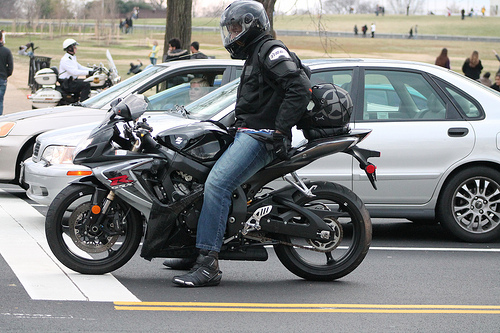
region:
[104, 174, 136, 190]
red R on the side of the motor bike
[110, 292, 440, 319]
double yellow line on the street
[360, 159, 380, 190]
red light on the back of bike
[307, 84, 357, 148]
extra helmet tied to the back of motorcycle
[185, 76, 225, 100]
woman with blonde hair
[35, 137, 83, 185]
front headlights are on in the front of car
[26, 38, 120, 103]
policeman riding on a motorcycle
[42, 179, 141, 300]
front black wheel on the white line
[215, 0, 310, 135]
rider is wearing a black jacket and helmet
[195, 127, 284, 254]
rider on motor bike is wearing blue jeans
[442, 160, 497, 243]
rear left tire on car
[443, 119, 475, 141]
black handle on door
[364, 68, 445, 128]
back window on car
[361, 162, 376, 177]
red light on back of motorcycle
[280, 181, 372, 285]
back tire on bike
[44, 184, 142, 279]
front tire on bike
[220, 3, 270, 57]
black helmet on head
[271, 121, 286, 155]
glove on left hand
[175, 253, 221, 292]
shoe on left foot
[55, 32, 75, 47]
white helmet on head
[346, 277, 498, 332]
a grey street with yellow lines.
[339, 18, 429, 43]
a bunch of people in the street.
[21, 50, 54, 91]
a big black garbage can.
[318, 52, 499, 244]
a grey car is parked.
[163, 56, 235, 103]
a woman sitting in a vehicle.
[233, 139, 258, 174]
a man is wearing blue jeans.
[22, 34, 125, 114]
a policeman is on a white motorcycle.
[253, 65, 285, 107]
a man is wearing a black jacket.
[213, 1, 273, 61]
a man is wearing a black and clear helmet.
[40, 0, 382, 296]
a man is sitting on the motorcycle.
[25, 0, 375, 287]
he is riding the motorcycle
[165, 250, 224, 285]
a couple of gray sneakers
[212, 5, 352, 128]
two gray helmets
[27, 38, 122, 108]
a police riding a white motorcycle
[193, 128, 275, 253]
he is wearing a blue jean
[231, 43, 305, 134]
wearing a black jacket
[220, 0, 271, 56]
the head of the rider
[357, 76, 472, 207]
the rear door of the car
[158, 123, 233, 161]
the gas tank of the motorcycle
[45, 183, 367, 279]
the two tires of the motorcycle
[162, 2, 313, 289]
Person wearing black shoes.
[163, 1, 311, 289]
Person wearing blue jeans.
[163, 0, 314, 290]
Person wearing a black jacket.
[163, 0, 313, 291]
Person wearing a black motorcycle helmet.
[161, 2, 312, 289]
Person sitting on a motorcycle.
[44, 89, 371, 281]
Motorcycle with two tires.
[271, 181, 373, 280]
Rear tire of a motorcycle.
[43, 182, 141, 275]
Front tire of a motorcycle.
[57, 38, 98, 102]
Person wearing a white shirt.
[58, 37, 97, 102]
Person wearing a white motorcycle helmet.